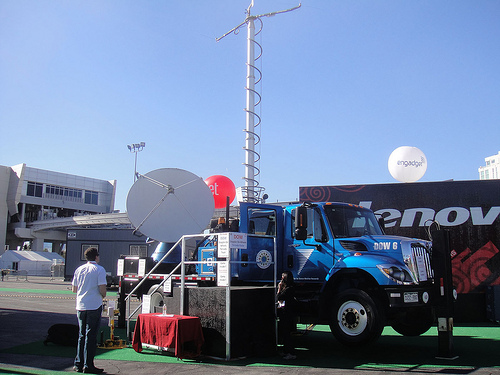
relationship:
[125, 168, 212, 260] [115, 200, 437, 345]
radar dish on truck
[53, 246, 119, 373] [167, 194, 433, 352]
lady standing next to truck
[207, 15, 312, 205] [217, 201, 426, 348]
antennae on truck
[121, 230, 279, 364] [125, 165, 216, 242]
staircase leading to satellite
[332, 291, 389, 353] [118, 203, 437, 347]
tire of blue truck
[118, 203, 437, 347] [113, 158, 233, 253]
blue truck next to satellite dish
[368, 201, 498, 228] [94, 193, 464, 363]
advertisement behind truck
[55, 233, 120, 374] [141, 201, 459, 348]
man looking at truck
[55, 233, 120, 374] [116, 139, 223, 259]
man looking at satellite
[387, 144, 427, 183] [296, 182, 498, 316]
balloons on top of sign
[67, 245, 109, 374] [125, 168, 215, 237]
man looking at dish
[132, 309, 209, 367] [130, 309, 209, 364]
cloth on top of table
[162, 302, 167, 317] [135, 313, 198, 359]
bottle on table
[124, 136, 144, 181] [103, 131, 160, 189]
lights on pole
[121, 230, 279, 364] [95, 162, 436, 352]
staircase next to truck